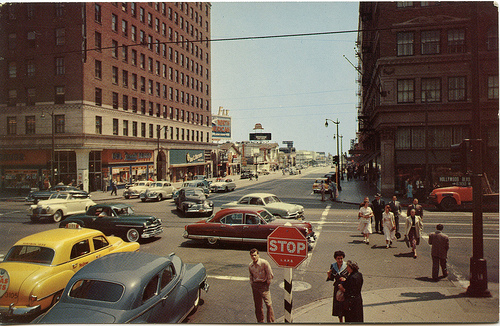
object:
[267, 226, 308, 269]
stop sign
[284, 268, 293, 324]
pole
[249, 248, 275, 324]
man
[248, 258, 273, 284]
shirt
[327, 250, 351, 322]
woman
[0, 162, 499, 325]
street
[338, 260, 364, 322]
woman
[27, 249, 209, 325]
car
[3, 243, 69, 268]
taxi cab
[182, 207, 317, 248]
car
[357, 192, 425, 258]
group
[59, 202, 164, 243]
car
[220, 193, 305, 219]
car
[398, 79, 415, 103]
window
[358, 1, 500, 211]
building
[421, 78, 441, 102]
window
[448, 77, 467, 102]
window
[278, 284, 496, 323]
sidewalk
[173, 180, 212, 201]
car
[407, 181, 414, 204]
people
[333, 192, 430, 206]
sidewalk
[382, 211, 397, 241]
dress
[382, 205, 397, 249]
woman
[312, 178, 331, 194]
vehicle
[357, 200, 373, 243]
woman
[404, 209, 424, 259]
people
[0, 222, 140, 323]
vehicles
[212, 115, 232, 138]
billboard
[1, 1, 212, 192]
building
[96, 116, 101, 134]
window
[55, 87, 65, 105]
window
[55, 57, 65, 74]
window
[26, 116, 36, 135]
window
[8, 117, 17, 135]
window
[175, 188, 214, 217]
vehicle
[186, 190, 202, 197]
window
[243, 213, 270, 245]
door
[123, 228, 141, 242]
tire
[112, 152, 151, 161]
lettering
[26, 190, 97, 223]
car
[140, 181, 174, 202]
car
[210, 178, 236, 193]
car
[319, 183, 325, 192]
shirt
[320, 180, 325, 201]
man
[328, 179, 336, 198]
man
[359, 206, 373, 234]
dress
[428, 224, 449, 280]
man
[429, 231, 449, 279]
suit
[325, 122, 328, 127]
light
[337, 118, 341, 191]
pole